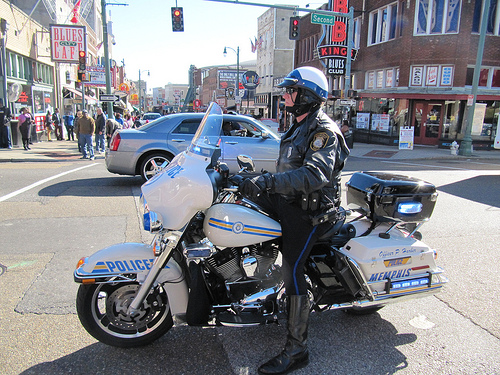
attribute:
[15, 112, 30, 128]
shirt — pink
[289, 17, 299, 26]
traffic signal — red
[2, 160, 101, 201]
line — white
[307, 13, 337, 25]
sign — green, white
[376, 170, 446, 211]
box — black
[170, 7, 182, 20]
signal — red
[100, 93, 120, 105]
sign — white, black